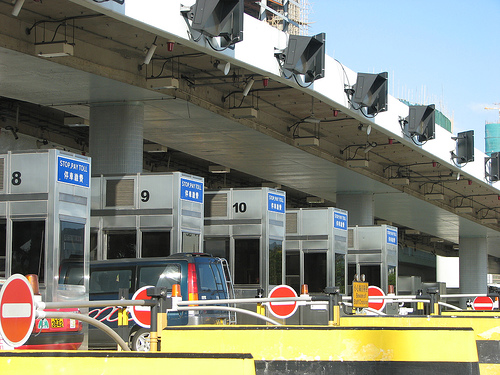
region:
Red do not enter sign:
[1, 274, 35, 346]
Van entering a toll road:
[65, 252, 234, 331]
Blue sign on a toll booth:
[56, 155, 90, 187]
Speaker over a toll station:
[349, 69, 389, 115]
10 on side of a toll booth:
[231, 201, 247, 213]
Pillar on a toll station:
[86, 99, 142, 179]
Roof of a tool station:
[1, 1, 498, 229]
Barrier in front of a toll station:
[164, 326, 480, 373]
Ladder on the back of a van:
[218, 256, 238, 325]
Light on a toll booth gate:
[171, 284, 180, 297]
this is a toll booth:
[20, 130, 497, 372]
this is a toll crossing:
[2, 130, 494, 373]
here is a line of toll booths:
[0, 125, 491, 370]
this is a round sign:
[0, 269, 62, 354]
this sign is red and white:
[0, 268, 44, 366]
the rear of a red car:
[20, 290, 109, 364]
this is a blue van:
[95, 233, 259, 361]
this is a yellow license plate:
[42, 305, 74, 339]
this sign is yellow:
[339, 268, 383, 310]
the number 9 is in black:
[134, 180, 161, 215]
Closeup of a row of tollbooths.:
[9, 11, 491, 363]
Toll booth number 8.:
[6, 144, 94, 286]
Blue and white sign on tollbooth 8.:
[5, 145, 91, 201]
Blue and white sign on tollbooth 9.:
[101, 171, 206, 211]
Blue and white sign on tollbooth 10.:
[223, 182, 288, 222]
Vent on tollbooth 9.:
[96, 170, 173, 219]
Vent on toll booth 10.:
[206, 185, 260, 223]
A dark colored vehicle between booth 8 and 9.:
[6, 140, 236, 332]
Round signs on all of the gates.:
[1, 263, 498, 323]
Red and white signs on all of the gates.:
[0, 265, 497, 345]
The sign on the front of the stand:
[56, 153, 93, 188]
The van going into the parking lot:
[78, 248, 242, 359]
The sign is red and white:
[261, 285, 304, 321]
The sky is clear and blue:
[174, 0, 499, 154]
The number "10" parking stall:
[209, 180, 291, 306]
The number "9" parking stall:
[93, 166, 208, 263]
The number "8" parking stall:
[3, 145, 94, 347]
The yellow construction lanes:
[143, 295, 495, 371]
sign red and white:
[267, 282, 298, 318]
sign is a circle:
[0, 272, 33, 346]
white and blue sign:
[56, 156, 89, 186]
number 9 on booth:
[141, 189, 148, 201]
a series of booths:
[0, 148, 399, 350]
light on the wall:
[397, 104, 435, 146]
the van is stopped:
[90, 250, 235, 352]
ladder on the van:
[220, 256, 237, 324]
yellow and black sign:
[352, 281, 366, 306]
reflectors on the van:
[186, 265, 197, 306]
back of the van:
[171, 253, 254, 330]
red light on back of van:
[169, 250, 219, 305]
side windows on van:
[72, 256, 197, 300]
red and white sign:
[0, 272, 66, 338]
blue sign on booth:
[157, 173, 214, 213]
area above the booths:
[169, 110, 443, 199]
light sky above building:
[364, 45, 495, 117]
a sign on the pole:
[122, 283, 166, 338]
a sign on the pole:
[254, 262, 322, 333]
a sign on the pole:
[350, 265, 377, 303]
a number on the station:
[232, 192, 247, 223]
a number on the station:
[8, 156, 38, 190]